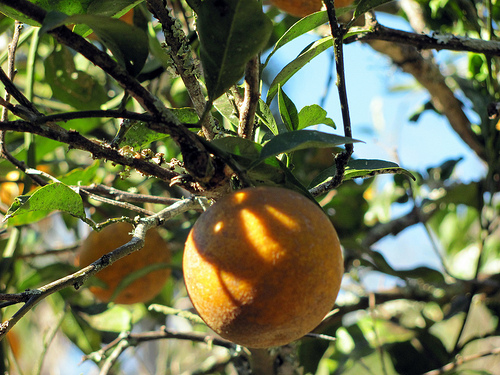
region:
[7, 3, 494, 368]
an orange tree has fruit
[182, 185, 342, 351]
the orange has tan markings on it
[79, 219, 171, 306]
a smaller orange has discoloration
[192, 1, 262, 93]
the leaves have white scale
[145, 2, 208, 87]
lichen are on the branches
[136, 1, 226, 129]
lichen indicates good air quality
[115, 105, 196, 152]
the leaf is diseased on the tree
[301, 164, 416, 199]
the leaf has a dark residue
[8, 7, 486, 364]
the fruit has dappled sunlight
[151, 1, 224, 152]
some branches are dead on the tree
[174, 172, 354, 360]
A large orange in a tree.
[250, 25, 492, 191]
a section of clear blue sky.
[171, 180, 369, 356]
a large orange in a tree.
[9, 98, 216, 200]
a branch in a tree with an orange.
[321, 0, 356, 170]
a small tree branch.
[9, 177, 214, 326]
a brown tree branch.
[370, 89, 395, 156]
a white object in a tree.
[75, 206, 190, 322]
an orange on a tree.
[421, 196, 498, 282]
leaves on a tree.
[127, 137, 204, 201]
flower buds on a tree branch.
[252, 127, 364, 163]
green leaf on tree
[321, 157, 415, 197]
green leaf on tree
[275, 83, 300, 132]
green leaf on tree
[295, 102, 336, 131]
green leaf on tree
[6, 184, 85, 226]
green leaf on tree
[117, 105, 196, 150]
green leaf on tree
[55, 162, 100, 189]
green leaf on tree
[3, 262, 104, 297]
green leaf on tree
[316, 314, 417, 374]
green leaf on tree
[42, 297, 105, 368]
green leaf on tree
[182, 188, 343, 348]
an orange fruit on tree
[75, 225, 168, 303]
an orange fruit on tree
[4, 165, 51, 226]
an orange fruit on tree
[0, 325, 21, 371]
an orange fruit on tree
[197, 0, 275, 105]
a green orange tree leaf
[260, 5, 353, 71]
a green orange tree leaf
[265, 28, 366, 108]
a green orange tree leaf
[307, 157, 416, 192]
a green orange tree leaf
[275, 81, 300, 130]
a green orange tree leaf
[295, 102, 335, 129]
a green orange tree leaf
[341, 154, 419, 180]
green leaf on tree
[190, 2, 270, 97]
green leaf on tree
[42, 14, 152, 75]
green leaf on tree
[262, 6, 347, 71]
green leaf on tree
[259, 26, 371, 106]
green leaf on tree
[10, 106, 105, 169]
green leaf on tree